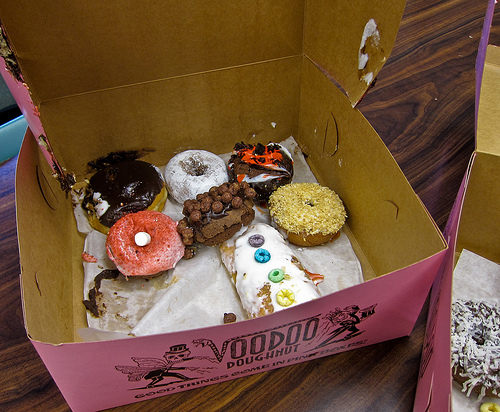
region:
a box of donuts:
[7, 5, 430, 396]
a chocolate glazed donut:
[91, 157, 164, 220]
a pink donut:
[109, 220, 178, 278]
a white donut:
[231, 223, 311, 314]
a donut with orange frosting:
[227, 143, 288, 193]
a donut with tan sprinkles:
[276, 178, 343, 247]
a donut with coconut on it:
[457, 300, 495, 377]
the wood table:
[266, 373, 385, 406]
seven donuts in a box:
[81, 136, 351, 309]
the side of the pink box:
[31, 253, 437, 403]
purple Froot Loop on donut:
[247, 232, 264, 246]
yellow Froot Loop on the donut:
[277, 287, 296, 304]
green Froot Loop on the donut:
[268, 267, 283, 281]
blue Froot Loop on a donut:
[255, 246, 270, 261]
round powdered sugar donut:
[166, 147, 227, 199]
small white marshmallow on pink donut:
[133, 230, 149, 244]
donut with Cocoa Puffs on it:
[180, 181, 259, 253]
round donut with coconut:
[268, 180, 345, 244]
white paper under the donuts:
[71, 135, 363, 337]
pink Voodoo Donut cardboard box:
[0, 2, 450, 409]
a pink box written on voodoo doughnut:
[211, 333, 303, 361]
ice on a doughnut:
[172, 168, 188, 188]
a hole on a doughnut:
[191, 162, 208, 177]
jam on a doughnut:
[109, 180, 127, 197]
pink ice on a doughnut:
[161, 228, 178, 260]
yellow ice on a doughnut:
[293, 211, 325, 226]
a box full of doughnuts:
[17, 57, 419, 317]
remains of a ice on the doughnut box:
[363, 15, 381, 45]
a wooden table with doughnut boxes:
[326, 370, 376, 400]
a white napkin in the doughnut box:
[155, 293, 200, 315]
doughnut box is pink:
[18, 237, 473, 398]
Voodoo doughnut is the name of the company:
[193, 306, 336, 381]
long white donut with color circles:
[245, 217, 310, 307]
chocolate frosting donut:
[82, 148, 178, 214]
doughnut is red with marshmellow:
[117, 205, 185, 282]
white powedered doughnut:
[157, 131, 248, 199]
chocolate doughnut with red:
[232, 130, 305, 191]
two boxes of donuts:
[288, 85, 491, 408]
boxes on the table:
[237, 73, 482, 403]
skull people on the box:
[151, 342, 205, 380]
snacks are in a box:
[111, 115, 380, 303]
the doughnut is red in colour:
[102, 204, 182, 275]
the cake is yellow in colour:
[268, 171, 334, 246]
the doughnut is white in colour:
[176, 132, 224, 192]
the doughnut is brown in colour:
[75, 166, 165, 209]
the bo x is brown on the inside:
[77, 10, 191, 126]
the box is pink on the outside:
[143, 339, 246, 378]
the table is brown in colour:
[206, 384, 313, 410]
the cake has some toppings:
[236, 218, 301, 313]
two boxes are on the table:
[0, 4, 499, 405]